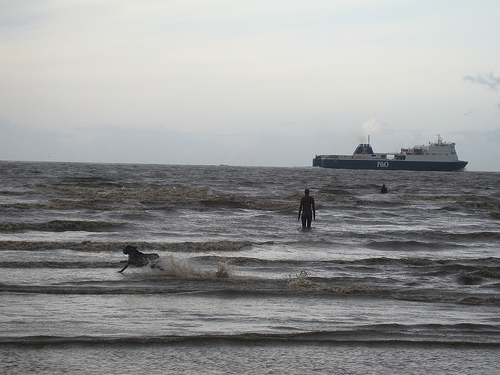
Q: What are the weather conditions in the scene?
A: It is overcast.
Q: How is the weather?
A: It is overcast.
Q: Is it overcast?
A: Yes, it is overcast.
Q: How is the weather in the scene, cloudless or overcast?
A: It is overcast.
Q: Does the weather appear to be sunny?
A: No, it is overcast.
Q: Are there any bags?
A: No, there are no bags.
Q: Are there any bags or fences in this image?
A: No, there are no bags or fences.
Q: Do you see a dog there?
A: Yes, there is a dog.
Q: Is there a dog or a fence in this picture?
A: Yes, there is a dog.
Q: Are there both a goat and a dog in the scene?
A: No, there is a dog but no goats.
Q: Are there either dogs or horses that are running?
A: Yes, the dog is running.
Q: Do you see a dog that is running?
A: Yes, there is a dog that is running.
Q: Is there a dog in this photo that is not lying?
A: Yes, there is a dog that is running.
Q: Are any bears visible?
A: No, there are no bears.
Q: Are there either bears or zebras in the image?
A: No, there are no bears or zebras.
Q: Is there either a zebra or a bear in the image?
A: No, there are no bears or zebras.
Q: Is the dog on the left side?
A: Yes, the dog is on the left of the image.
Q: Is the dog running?
A: Yes, the dog is running.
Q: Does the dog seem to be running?
A: Yes, the dog is running.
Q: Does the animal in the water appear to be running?
A: Yes, the dog is running.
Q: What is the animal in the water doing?
A: The dog is running.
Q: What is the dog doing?
A: The dog is running.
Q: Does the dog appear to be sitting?
A: No, the dog is running.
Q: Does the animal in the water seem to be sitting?
A: No, the dog is running.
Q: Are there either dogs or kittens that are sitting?
A: No, there is a dog but it is running.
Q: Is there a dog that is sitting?
A: No, there is a dog but it is running.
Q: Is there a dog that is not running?
A: No, there is a dog but it is running.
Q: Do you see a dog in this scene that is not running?
A: No, there is a dog but it is running.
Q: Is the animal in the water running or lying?
A: The dog is running.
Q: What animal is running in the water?
A: The dog is running in the water.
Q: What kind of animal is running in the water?
A: The animal is a dog.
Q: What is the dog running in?
A: The dog is running in the water.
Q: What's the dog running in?
A: The dog is running in the water.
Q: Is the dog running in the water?
A: Yes, the dog is running in the water.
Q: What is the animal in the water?
A: The animal is a dog.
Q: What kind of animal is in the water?
A: The animal is a dog.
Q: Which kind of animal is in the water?
A: The animal is a dog.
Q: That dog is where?
A: The dog is in the water.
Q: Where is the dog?
A: The dog is in the water.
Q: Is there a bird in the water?
A: No, there is a dog in the water.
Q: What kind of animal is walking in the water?
A: The animal is a dog.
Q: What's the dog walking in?
A: The dog is walking in the water.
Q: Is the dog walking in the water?
A: Yes, the dog is walking in the water.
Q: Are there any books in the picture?
A: No, there are no books.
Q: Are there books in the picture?
A: No, there are no books.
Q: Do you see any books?
A: No, there are no books.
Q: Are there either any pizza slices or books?
A: No, there are no books or pizza slices.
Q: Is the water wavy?
A: Yes, the water is wavy.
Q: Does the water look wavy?
A: Yes, the water is wavy.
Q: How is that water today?
A: The water is wavy.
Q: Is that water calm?
A: No, the water is wavy.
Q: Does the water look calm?
A: No, the water is wavy.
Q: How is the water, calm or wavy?
A: The water is wavy.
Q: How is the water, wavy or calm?
A: The water is wavy.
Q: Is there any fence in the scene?
A: No, there are no fences.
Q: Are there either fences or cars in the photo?
A: No, there are no fences or cars.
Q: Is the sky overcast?
A: Yes, the sky is overcast.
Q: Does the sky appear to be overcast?
A: Yes, the sky is overcast.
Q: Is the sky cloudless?
A: No, the sky is overcast.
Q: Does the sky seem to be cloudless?
A: No, the sky is overcast.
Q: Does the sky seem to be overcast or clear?
A: The sky is overcast.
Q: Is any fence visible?
A: No, there are no fences.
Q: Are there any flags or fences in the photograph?
A: No, there are no fences or flags.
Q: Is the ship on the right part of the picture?
A: Yes, the ship is on the right of the image.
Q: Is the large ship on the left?
A: No, the ship is on the right of the image.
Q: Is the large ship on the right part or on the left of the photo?
A: The ship is on the right of the image.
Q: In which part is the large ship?
A: The ship is on the right of the image.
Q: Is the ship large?
A: Yes, the ship is large.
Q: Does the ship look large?
A: Yes, the ship is large.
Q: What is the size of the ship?
A: The ship is large.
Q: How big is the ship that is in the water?
A: The ship is large.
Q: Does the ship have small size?
A: No, the ship is large.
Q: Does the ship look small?
A: No, the ship is large.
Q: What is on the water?
A: The ship is on the water.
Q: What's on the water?
A: The ship is on the water.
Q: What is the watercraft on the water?
A: The watercraft is a ship.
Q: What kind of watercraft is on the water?
A: The watercraft is a ship.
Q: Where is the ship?
A: The ship is on the water.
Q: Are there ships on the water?
A: Yes, there is a ship on the water.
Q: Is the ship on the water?
A: Yes, the ship is on the water.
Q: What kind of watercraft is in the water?
A: The watercraft is a ship.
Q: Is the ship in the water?
A: Yes, the ship is in the water.